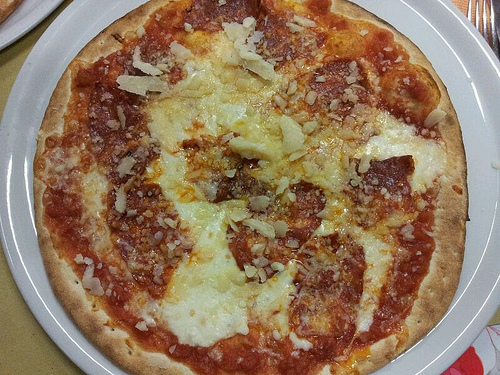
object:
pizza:
[32, 0, 468, 374]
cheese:
[33, 1, 444, 372]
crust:
[29, 0, 469, 375]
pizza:
[1, 0, 22, 24]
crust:
[0, 0, 22, 24]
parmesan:
[491, 159, 500, 170]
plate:
[0, 0, 500, 375]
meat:
[85, 0, 416, 360]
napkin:
[442, 324, 500, 374]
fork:
[463, 0, 500, 58]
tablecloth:
[0, 234, 84, 375]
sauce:
[38, 0, 447, 373]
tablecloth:
[0, 0, 500, 374]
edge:
[40, 0, 195, 375]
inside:
[18, 0, 498, 374]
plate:
[0, 0, 66, 48]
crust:
[44, 154, 179, 374]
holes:
[73, 280, 130, 357]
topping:
[118, 1, 369, 13]